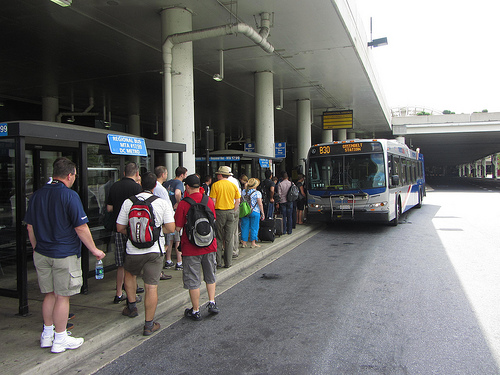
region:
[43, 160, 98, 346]
person on the sidewalk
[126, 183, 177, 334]
person on the sidewalk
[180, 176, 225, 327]
person on the sidewalk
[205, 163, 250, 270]
person on the sidewalk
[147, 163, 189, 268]
person on the sidewalk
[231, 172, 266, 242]
person on the sidewalk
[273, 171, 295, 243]
person on the sidewalk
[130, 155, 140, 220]
person on the sidewalk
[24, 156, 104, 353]
man holding a clear water bottle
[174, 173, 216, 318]
man wearing a black hat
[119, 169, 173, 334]
man with a gray, red, and black backpack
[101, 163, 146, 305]
man wearing flannel shorts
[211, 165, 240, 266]
man wearing a yellow shirt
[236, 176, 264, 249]
woman wearing blue pants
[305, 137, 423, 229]
gray and blue bus at the stop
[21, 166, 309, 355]
line of people waiting to get on the bus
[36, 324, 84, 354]
white shoes on the man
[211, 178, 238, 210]
yellow shirt on the man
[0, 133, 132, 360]
this is a person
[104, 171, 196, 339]
this is a person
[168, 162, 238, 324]
this is a person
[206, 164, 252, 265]
this is a person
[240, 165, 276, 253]
this is a person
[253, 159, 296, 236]
this is a person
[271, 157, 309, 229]
this is a person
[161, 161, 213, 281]
this is a person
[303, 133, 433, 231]
blue, gray and white bus parked near curb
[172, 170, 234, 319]
man red shirt and backpack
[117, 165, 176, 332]
man in white shirt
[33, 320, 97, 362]
white tennis shoes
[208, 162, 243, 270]
man wearing yellow shirt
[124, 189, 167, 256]
red,gray and black back pack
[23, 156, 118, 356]
man wearing green shorts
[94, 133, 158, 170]
blue sign with white letters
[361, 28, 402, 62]
light above bus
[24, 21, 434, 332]
this is an outside setting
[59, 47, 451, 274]
this is a transit station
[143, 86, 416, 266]
this is at a bus stop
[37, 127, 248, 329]
this is a crowd of people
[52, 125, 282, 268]
the people are waiting for the bus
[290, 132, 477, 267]
this is a bus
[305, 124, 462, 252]
this is a passenger bus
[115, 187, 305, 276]
these men have on backpacks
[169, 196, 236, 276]
the man has a red shirt on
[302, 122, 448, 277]
the bus is silver and blue